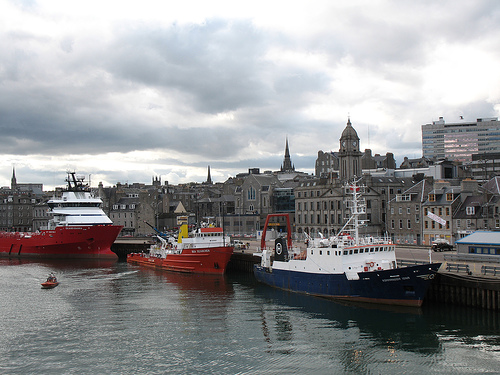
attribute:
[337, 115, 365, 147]
top — domed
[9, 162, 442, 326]
boat — blue, white, small, parked, red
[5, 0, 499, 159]
cloud — white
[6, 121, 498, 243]
window — small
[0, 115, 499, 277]
building — tall, white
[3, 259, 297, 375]
ripples — small